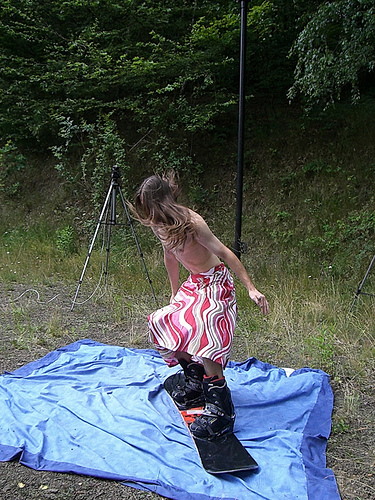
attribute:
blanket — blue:
[8, 320, 339, 497]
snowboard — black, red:
[162, 374, 263, 476]